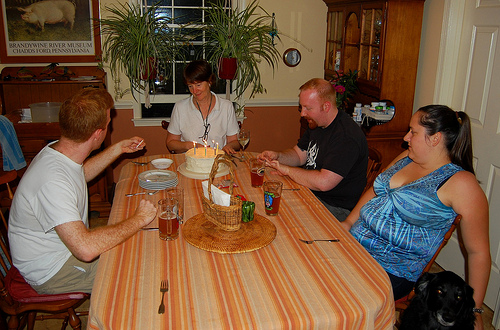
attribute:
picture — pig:
[0, 6, 107, 66]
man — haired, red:
[18, 93, 148, 299]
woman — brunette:
[321, 87, 498, 308]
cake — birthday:
[178, 137, 230, 184]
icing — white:
[184, 162, 211, 174]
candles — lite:
[189, 139, 219, 154]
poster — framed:
[2, 3, 112, 75]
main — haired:
[275, 75, 355, 146]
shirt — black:
[307, 129, 360, 194]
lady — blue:
[381, 95, 472, 246]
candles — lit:
[179, 132, 252, 180]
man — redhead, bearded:
[273, 82, 368, 215]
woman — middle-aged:
[166, 56, 243, 156]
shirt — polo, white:
[164, 89, 239, 149]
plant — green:
[192, 2, 280, 98]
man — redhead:
[46, 87, 131, 172]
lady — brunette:
[338, 82, 494, 319]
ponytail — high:
[453, 106, 482, 190]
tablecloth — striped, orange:
[108, 241, 460, 328]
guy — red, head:
[4, 89, 157, 296]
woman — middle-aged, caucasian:
[166, 60, 238, 152]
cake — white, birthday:
[184, 148, 214, 178]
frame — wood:
[1, 2, 101, 80]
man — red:
[282, 80, 354, 198]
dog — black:
[415, 266, 476, 328]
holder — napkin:
[193, 148, 251, 236]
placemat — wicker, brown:
[193, 223, 225, 247]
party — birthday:
[65, 58, 480, 299]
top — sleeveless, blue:
[370, 160, 443, 270]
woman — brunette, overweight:
[365, 96, 484, 319]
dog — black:
[404, 276, 460, 327]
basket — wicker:
[197, 163, 240, 229]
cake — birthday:
[185, 140, 214, 186]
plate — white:
[188, 172, 191, 178]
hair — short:
[312, 87, 336, 97]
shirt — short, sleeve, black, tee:
[305, 130, 366, 197]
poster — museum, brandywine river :
[8, 4, 98, 52]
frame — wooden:
[42, 55, 111, 63]